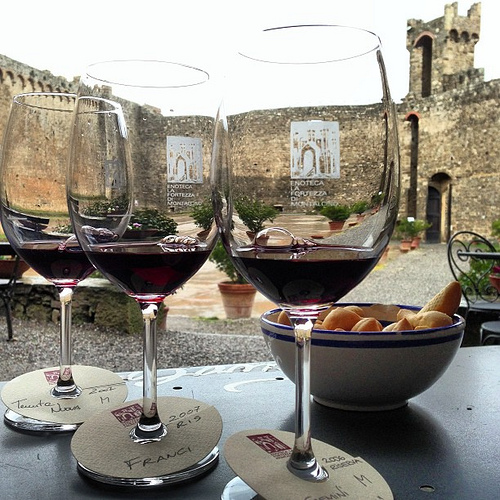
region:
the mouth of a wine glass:
[229, 20, 389, 77]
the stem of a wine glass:
[273, 303, 328, 470]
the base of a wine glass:
[70, 415, 226, 492]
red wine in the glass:
[221, 233, 391, 311]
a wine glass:
[215, 15, 403, 498]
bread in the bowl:
[416, 275, 468, 322]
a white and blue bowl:
[254, 295, 471, 417]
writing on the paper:
[115, 440, 197, 473]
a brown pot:
[216, 275, 259, 327]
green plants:
[396, 209, 433, 242]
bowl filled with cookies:
[339, 288, 455, 383]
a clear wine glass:
[200, 20, 407, 496]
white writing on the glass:
[260, 110, 367, 249]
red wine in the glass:
[215, 126, 387, 313]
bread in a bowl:
[254, 287, 476, 361]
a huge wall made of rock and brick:
[0, 59, 479, 230]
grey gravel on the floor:
[57, 324, 222, 363]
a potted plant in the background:
[197, 186, 254, 312]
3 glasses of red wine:
[2, 37, 351, 461]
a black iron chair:
[445, 211, 498, 344]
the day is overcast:
[37, 21, 487, 202]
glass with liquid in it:
[239, 143, 396, 279]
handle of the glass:
[253, 313, 335, 453]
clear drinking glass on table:
[210, 70, 388, 224]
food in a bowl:
[347, 271, 472, 393]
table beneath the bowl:
[391, 421, 466, 485]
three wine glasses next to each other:
[1, 129, 394, 294]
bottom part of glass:
[108, 387, 209, 463]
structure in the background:
[400, 13, 485, 95]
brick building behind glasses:
[439, 112, 490, 157]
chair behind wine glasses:
[443, 218, 498, 335]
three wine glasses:
[6, 20, 398, 394]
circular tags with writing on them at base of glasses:
[7, 362, 376, 499]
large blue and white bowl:
[256, 280, 471, 418]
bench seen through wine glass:
[0, 195, 64, 248]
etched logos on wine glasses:
[151, 107, 351, 217]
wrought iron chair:
[445, 223, 499, 343]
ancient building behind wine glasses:
[1, 3, 496, 271]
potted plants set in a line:
[193, 166, 434, 329]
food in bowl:
[265, 278, 464, 361]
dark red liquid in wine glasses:
[17, 192, 389, 313]